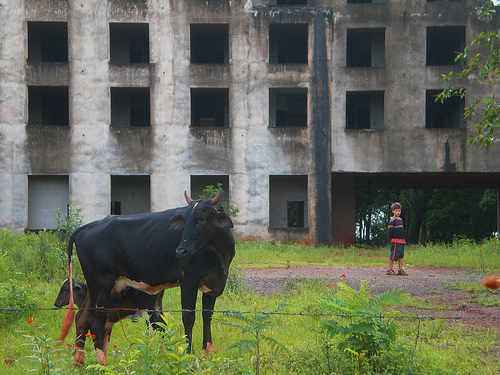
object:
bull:
[56, 186, 236, 370]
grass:
[265, 316, 319, 351]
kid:
[386, 202, 406, 275]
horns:
[183, 187, 223, 206]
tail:
[55, 231, 76, 345]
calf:
[52, 277, 165, 360]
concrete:
[294, 12, 338, 25]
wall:
[155, 8, 187, 87]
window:
[27, 20, 73, 63]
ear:
[165, 213, 185, 231]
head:
[175, 198, 223, 259]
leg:
[179, 281, 199, 355]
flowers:
[15, 312, 51, 362]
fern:
[309, 280, 422, 358]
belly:
[120, 275, 180, 295]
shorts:
[388, 242, 404, 261]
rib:
[130, 224, 161, 240]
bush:
[219, 305, 293, 371]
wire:
[0, 306, 500, 320]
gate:
[354, 173, 499, 254]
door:
[286, 201, 305, 228]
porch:
[227, 174, 270, 236]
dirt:
[246, 267, 285, 295]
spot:
[193, 202, 199, 210]